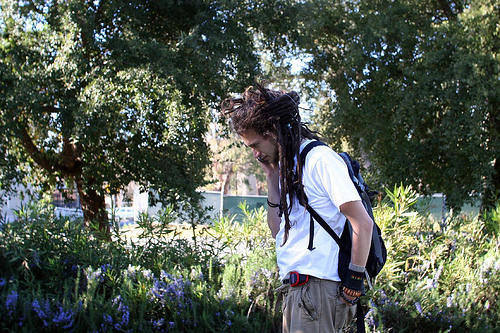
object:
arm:
[266, 176, 288, 238]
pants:
[279, 273, 356, 333]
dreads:
[218, 81, 325, 246]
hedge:
[0, 161, 217, 242]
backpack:
[336, 150, 388, 294]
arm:
[319, 153, 374, 266]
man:
[227, 79, 373, 333]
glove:
[339, 265, 370, 298]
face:
[238, 130, 276, 165]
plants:
[0, 212, 279, 326]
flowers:
[0, 180, 500, 333]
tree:
[0, 0, 285, 241]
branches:
[2, 1, 499, 212]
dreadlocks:
[220, 76, 336, 247]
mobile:
[257, 154, 268, 163]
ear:
[265, 130, 283, 145]